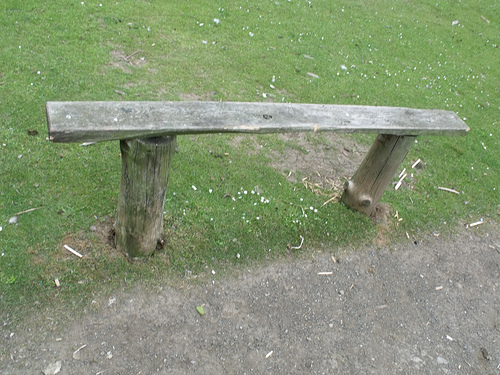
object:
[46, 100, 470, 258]
bench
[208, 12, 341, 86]
grass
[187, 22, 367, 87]
debris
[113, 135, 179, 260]
stump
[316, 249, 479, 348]
trail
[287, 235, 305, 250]
litter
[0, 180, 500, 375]
ground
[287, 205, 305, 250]
twig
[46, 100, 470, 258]
log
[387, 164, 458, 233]
leaf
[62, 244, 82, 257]
trash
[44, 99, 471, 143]
board